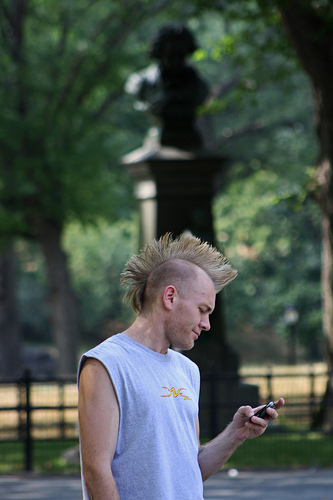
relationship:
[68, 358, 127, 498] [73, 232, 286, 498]
arm of man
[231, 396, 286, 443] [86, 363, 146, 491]
hand of man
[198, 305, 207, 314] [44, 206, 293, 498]
eye of person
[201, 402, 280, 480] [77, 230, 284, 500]
hand of man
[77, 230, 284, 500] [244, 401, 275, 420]
man holding phone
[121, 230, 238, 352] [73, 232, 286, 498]
head of man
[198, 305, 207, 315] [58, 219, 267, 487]
eye of man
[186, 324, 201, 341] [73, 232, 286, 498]
mouth of man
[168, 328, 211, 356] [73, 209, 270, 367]
chin of man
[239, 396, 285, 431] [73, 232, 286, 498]
fingers of man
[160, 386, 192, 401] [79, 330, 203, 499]
graphics on shirt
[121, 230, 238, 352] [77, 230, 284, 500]
head of man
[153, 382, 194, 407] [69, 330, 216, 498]
graphics of shirt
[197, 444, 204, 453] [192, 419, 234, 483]
tattoo on arm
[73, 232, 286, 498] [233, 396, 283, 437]
man left hand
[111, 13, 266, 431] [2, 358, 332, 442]
statue behind fence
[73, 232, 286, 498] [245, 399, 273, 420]
man texting cellphone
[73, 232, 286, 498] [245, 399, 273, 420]
man on h cellphone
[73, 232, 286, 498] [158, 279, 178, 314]
man has ear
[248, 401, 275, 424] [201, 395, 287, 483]
cell phone in arm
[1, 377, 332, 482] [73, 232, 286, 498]
railing behind man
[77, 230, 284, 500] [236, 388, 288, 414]
man on phone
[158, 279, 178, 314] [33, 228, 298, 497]
ear of person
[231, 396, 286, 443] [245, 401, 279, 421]
hand holding phone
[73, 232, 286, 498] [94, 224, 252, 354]
man with mohalk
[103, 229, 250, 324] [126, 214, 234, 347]
mohawk on head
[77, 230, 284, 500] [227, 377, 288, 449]
man looking down at phone